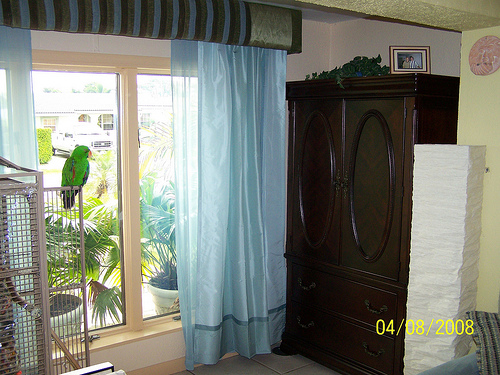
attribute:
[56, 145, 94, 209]
bird — green, standing, a parrot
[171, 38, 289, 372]
curtain — sheer, blue, long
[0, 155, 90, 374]
cage — gray, metal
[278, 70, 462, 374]
dresser — large, wooden, brown, wood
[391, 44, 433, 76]
photo — framed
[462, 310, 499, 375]
pillow — striped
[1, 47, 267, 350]
window — large, wall length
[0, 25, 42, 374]
curtain — blue, hanging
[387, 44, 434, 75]
frame — gold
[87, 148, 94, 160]
beak — yellow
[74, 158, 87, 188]
feather — green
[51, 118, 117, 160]
vehicle — white, parked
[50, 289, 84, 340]
planter — white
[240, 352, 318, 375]
tile — tan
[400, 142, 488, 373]
lamp shade — white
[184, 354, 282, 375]
tile — white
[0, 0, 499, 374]
room scene — interior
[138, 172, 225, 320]
plant — potted